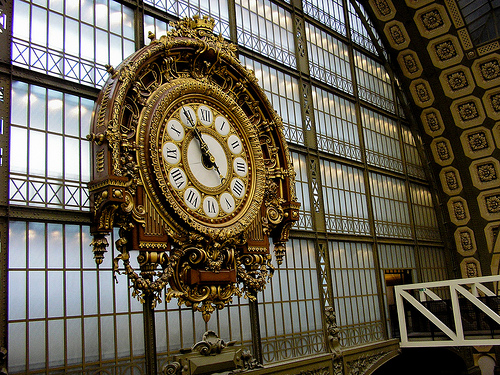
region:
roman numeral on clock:
[195, 100, 215, 130]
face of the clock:
[155, 91, 250, 256]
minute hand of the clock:
[181, 86, 196, 157]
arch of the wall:
[380, 335, 407, 371]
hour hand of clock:
[205, 145, 230, 185]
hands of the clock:
[170, 115, 235, 195]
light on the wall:
[45, 225, 60, 245]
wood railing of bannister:
[385, 265, 490, 300]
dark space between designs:
[445, 125, 460, 150]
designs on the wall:
[435, 110, 490, 262]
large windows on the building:
[261, 74, 380, 236]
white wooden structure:
[377, 245, 493, 367]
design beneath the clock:
[88, 225, 310, 302]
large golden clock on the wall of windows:
[78, 5, 343, 342]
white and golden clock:
[145, 83, 276, 242]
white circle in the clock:
[181, 124, 241, 189]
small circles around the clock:
[183, 180, 265, 241]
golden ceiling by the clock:
[412, 34, 497, 147]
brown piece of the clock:
[182, 257, 261, 291]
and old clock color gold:
[72, 8, 311, 325]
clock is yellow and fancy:
[70, 11, 312, 333]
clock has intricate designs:
[74, 9, 310, 325]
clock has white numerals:
[148, 88, 257, 228]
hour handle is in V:
[205, 150, 240, 216]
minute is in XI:
[173, 95, 218, 161]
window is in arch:
[16, 7, 452, 361]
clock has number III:
[223, 154, 253, 180]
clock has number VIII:
[162, 162, 192, 194]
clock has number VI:
[200, 192, 224, 220]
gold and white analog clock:
[162, 98, 252, 237]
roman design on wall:
[401, 24, 486, 159]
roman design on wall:
[431, 40, 491, 232]